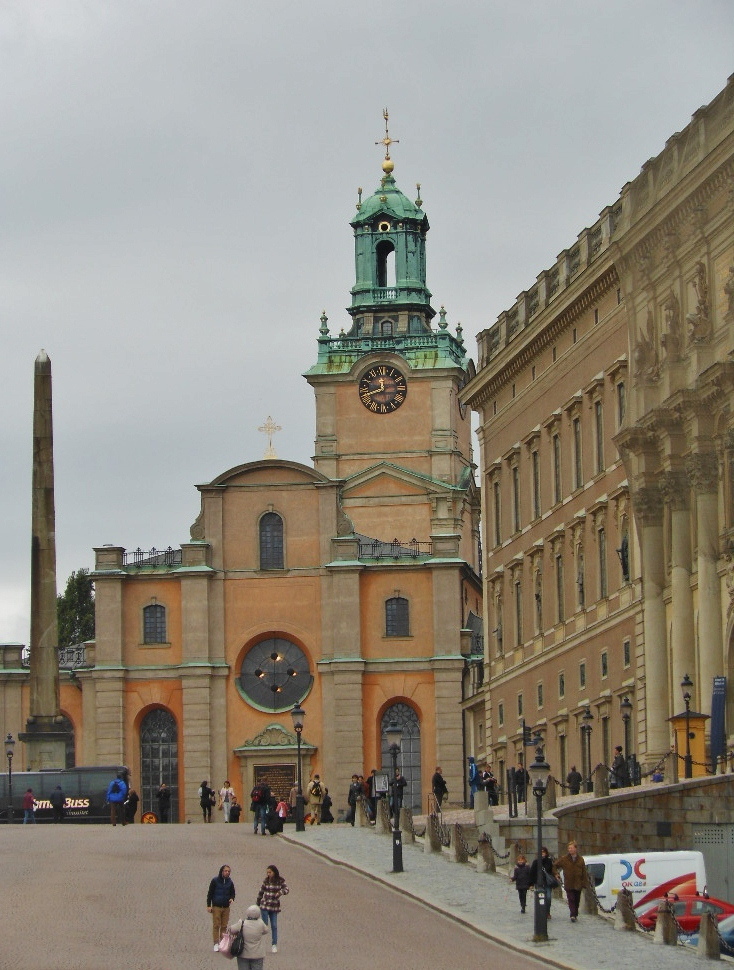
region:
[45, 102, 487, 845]
large tan and orange building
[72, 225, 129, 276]
white clouds in blue sky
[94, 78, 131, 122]
white clouds in blue sky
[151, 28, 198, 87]
white clouds in blue sky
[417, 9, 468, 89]
white clouds in blue sky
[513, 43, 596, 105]
white clouds in blue sky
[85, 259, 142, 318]
white clouds in blue sky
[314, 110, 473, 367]
the green tower on a building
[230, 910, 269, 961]
a person wearing a white coat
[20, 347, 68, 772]
a brown stone obelisk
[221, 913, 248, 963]
a person carrying a black shoulder bag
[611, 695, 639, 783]
a street lamp on a post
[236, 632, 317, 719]
a circular window on a building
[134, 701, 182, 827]
an arched window on a building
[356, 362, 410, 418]
a clock on a building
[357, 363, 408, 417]
a clock face with roman numerals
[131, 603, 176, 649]
a window on a building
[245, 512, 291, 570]
a window on a building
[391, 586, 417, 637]
a window on a building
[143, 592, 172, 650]
a window on a building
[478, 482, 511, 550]
a window on a building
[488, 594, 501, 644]
a window on a building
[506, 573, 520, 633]
a window on a building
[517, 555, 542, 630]
a window on a building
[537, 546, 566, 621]
a window on a building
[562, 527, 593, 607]
a window on a building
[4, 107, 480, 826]
the church is ornate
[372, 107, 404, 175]
a gold cross is on top of the tower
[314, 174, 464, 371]
the top of the tower has a green patina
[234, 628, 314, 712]
the church has a large round window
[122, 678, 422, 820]
there are two large arched windows by the doorway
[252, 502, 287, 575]
a smaller arched window is over the round window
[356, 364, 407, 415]
a large public clock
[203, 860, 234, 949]
a man walking on street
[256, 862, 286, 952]
a woman walking on street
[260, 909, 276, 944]
a pair of blue jeans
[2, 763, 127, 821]
a large black bus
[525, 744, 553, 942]
an ornate street light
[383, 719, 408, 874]
an ornate street light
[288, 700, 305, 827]
an ornate street light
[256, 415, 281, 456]
a golden cross in distance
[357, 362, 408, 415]
clock is on front of building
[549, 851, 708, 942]
vehicle is parked near building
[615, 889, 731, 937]
car is parked near building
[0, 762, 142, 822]
bus parked near building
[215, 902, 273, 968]
human slings bag over shoulder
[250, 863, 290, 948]
human wears jacket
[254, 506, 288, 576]
window on front of building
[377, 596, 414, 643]
window on front of building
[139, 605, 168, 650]
window on front of building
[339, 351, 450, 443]
clock on top of tower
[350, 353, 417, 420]
clock has black face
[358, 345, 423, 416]
clock has yellow hands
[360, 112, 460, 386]
top of tower is green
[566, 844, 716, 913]
van is white in color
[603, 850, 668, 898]
logo on side of van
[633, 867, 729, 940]
car is red in color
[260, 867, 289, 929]
person is wearing plaid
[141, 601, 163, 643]
a window on a building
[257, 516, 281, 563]
a window on a building